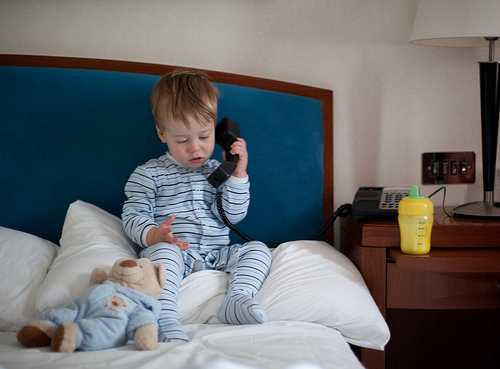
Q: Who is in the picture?
A: A boy.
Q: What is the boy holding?
A: A telephone.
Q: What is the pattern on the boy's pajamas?
A: Striped.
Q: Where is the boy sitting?
A: A bed.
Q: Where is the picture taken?
A: A bedroom.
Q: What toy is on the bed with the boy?
A: Teddy bear.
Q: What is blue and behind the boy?
A: The headboard.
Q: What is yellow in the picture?
A: A sippy cup.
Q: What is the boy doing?
A: Talking.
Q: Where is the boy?
A: In bed.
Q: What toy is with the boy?
A: Teddy bear.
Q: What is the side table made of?
A: Wood.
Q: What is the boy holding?
A: Phone.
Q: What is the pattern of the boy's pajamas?
A: Striped.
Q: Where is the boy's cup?
A: On the side table.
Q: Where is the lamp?
A: On the side table.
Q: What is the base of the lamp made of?
A: Metal.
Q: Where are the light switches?
A: On the wall near the bedside table.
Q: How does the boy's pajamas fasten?
A: Snaps.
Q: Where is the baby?
A: On the bed.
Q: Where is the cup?
A: On the table.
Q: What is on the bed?
A: Teddy bear.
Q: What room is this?
A: Bedroom.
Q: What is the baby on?
A: Pillow.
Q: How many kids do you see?
A: 1 child.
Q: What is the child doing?
A: Holding the phone.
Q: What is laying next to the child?
A: A stuffed animal.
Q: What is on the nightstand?
A: A sip cup.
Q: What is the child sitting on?
A: A pillow.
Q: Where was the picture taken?
A: In a bedroom.